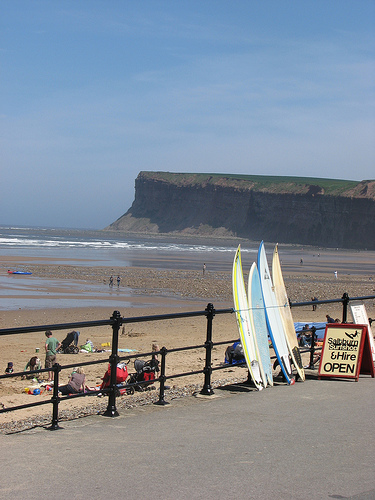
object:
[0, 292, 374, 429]
rails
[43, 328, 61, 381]
man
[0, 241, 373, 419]
beach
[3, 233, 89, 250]
water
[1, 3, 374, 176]
sky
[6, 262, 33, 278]
boat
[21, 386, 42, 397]
toy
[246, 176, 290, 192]
grass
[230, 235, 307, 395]
surfboards